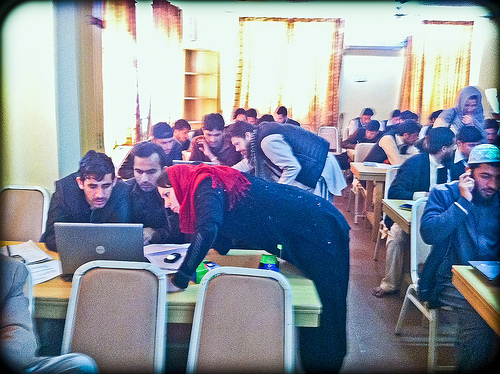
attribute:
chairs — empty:
[70, 256, 323, 364]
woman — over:
[154, 160, 342, 275]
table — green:
[15, 294, 316, 325]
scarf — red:
[162, 161, 231, 222]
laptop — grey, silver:
[50, 216, 145, 257]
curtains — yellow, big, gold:
[240, 20, 335, 111]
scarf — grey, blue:
[446, 79, 484, 123]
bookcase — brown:
[173, 42, 224, 119]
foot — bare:
[369, 282, 399, 305]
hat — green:
[465, 140, 496, 163]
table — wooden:
[355, 152, 383, 179]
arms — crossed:
[386, 141, 415, 163]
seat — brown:
[214, 294, 268, 370]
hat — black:
[149, 123, 172, 135]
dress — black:
[206, 178, 347, 281]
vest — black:
[255, 121, 329, 190]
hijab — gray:
[324, 163, 342, 193]